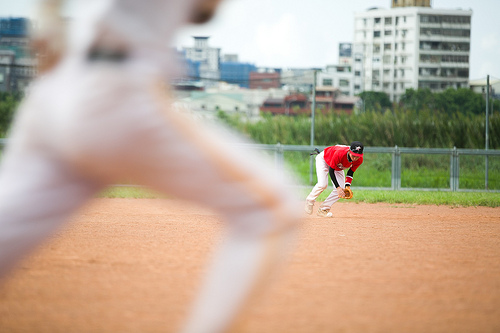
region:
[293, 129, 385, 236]
player on the field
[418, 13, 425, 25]
window on the building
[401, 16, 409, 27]
window on the building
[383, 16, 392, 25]
window on the building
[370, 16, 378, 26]
window on the building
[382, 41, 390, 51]
window on the building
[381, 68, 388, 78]
window on the building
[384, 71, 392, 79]
window on the building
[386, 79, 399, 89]
window on the building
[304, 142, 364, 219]
a baseball player in a field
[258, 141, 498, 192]
a gray metal fence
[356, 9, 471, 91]
a white multi-stories building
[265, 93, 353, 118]
a red brick building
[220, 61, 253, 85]
a blue building in the distance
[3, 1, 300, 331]
baseball player wearing a white uniform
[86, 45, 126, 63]
a black belt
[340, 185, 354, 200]
a catcher's mitt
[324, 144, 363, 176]
man wearing a red shirt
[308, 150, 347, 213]
man wearing white pants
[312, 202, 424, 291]
the field is brown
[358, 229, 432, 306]
the field is brown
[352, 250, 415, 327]
the field is brown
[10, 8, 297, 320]
the player is trying to run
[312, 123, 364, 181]
the jersey is red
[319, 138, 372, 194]
the jersey is red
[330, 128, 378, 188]
player is wearing a cap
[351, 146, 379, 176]
fielder has black cap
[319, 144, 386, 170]
fielder has red shirt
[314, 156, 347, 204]
fielder has white pants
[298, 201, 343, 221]
fielder has white shoes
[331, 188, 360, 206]
fielder has brown glove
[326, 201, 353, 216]
white ball near fielder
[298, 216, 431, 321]
infield dirt is brown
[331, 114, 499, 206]
grey fence in outfield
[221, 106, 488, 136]
long green grass past fence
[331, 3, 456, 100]
tall and white building